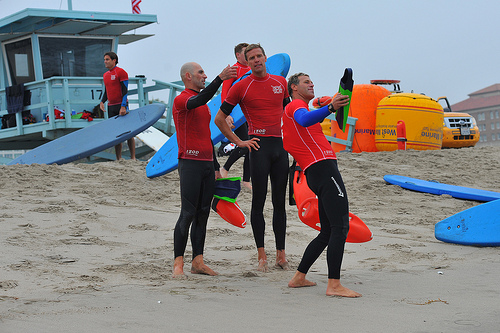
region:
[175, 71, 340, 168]
the men wear red tops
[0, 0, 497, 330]
the men are at the beach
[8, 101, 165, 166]
the man holds a board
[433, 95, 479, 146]
the vehicle is yellow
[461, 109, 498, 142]
the building has many windows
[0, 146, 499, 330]
the sand has foot prints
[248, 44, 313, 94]
the men have short hair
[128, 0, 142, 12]
the american flag waves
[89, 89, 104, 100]
the building has number 17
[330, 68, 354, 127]
the man holds a green object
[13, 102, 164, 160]
long blue surf boat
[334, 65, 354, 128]
green and black flipper shoe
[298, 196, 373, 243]
orange safety float in hand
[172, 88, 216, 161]
red nylon wet suit shirt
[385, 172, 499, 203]
blue surf board on sand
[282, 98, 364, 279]
red blue and black wet suit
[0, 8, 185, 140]
blue wood life guard stand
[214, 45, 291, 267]
man wearing wet suit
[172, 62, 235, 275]
man holding flipper shoe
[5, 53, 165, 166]
man holding surf board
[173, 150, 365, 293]
The men are wearing black pants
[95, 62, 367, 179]
The men are wearing red shirts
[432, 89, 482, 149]
Yellow car in background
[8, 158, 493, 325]
The picture is taken at the beach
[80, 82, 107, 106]
The number 17 is on the lifeguard station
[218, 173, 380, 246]
The lifeguards are holding red life perservers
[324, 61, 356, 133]
Man is holding a green flipper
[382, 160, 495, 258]
There are 2 blue surfboards on the sand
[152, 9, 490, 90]
Weather is cloudy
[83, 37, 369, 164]
There are 5 lifeguards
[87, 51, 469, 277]
men on the beach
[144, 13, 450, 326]
men on the sand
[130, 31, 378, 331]
men standing on the beach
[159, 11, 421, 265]
men standing on the sand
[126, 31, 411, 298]
men wearing red shirts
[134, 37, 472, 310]
men wearing black pants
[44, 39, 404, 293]
surfboards on the beach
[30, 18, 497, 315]
surfboards on the sand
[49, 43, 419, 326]
a beach with sand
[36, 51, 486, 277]
a beach with surfboards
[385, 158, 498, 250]
Two blue surf boards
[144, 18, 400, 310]
Surfers posing on the beach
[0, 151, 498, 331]
Dry sand on the beach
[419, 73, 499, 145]
Building with red roof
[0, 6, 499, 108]
Dark storm clouds bringing rain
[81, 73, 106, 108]
Number seventeen on building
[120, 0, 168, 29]
Part of an American flag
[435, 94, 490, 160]
Yellow pick up truck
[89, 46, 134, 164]
Man wearing red and black wet suit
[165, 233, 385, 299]
Three sets of bare feet